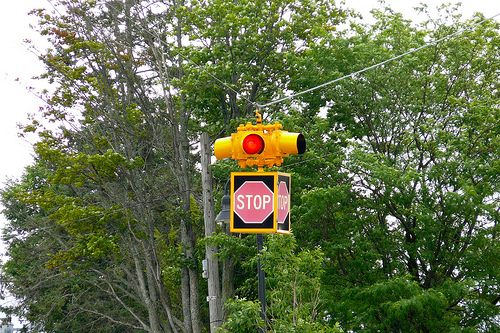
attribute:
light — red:
[243, 131, 276, 171]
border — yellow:
[268, 172, 294, 221]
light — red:
[239, 130, 266, 156]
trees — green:
[2, 0, 482, 330]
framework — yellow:
[211, 106, 310, 169]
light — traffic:
[236, 130, 266, 158]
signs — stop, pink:
[233, 178, 293, 226]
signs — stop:
[231, 173, 292, 231]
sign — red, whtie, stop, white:
[232, 179, 274, 223]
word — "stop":
[234, 191, 270, 211]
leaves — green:
[354, 278, 450, 328]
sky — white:
[0, 2, 92, 184]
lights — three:
[211, 108, 308, 168]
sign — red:
[234, 180, 273, 222]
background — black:
[232, 173, 275, 229]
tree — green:
[164, 110, 401, 331]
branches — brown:
[125, 184, 198, 330]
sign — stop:
[231, 175, 273, 229]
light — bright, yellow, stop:
[211, 105, 307, 170]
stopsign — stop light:
[228, 163, 294, 232]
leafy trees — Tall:
[38, 10, 452, 315]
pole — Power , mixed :
[182, 151, 284, 314]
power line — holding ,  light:
[173, 88, 373, 309]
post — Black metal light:
[229, 227, 285, 318]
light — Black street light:
[201, 120, 309, 226]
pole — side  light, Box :
[247, 241, 273, 322]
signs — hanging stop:
[222, 179, 295, 226]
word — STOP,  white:
[226, 180, 281, 228]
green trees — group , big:
[22, 6, 450, 308]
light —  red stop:
[204, 117, 320, 241]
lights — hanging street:
[215, 112, 301, 189]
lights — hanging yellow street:
[204, 130, 307, 237]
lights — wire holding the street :
[214, 110, 305, 234]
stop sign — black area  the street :
[214, 166, 294, 234]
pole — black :
[243, 254, 284, 322]